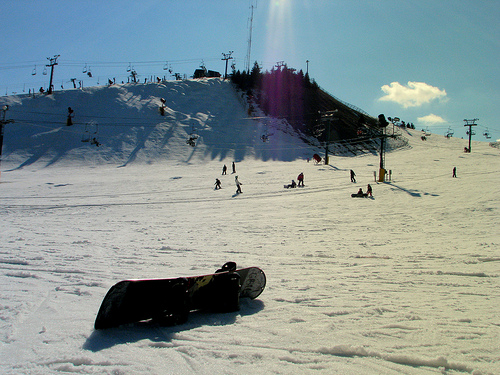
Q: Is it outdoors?
A: Yes, it is outdoors.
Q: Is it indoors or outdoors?
A: It is outdoors.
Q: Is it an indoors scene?
A: No, it is outdoors.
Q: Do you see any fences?
A: Yes, there is a fence.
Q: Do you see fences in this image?
A: Yes, there is a fence.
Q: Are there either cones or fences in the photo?
A: Yes, there is a fence.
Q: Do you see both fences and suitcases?
A: No, there is a fence but no suitcases.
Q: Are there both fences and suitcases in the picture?
A: No, there is a fence but no suitcases.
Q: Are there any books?
A: No, there are no books.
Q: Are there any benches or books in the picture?
A: No, there are no books or benches.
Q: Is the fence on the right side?
A: Yes, the fence is on the right of the image.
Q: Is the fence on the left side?
A: No, the fence is on the right of the image.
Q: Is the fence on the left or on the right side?
A: The fence is on the right of the image.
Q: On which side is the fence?
A: The fence is on the right of the image.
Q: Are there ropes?
A: No, there are no ropes.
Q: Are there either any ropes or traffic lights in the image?
A: No, there are no ropes or traffic lights.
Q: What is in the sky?
A: The clouds are in the sky.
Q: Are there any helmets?
A: No, there are no helmets.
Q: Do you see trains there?
A: No, there are no trains.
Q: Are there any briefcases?
A: No, there are no briefcases.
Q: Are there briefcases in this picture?
A: No, there are no briefcases.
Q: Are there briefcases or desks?
A: No, there are no briefcases or desks.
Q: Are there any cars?
A: No, there are no cars.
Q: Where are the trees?
A: The trees are on the hill.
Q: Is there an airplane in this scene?
A: No, there are no airplanes.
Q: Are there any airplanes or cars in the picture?
A: No, there are no airplanes or cars.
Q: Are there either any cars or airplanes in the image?
A: No, there are no airplanes or cars.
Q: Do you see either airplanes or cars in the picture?
A: No, there are no airplanes or cars.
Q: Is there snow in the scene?
A: Yes, there is snow.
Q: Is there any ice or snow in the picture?
A: Yes, there is snow.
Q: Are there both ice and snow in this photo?
A: No, there is snow but no ice.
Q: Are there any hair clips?
A: No, there are no hair clips.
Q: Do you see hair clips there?
A: No, there are no hair clips.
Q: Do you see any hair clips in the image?
A: No, there are no hair clips.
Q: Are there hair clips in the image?
A: No, there are no hair clips.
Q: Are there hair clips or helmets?
A: No, there are no hair clips or helmets.